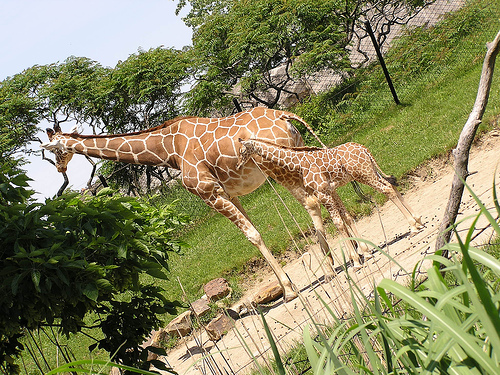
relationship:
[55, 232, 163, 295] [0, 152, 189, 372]
leaves on tree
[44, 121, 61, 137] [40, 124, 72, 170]
horn on top head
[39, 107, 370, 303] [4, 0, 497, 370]
giraffe in enclosure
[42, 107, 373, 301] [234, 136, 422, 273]
giraffe protecting giraffe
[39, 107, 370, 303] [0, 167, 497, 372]
giraffe close to bushes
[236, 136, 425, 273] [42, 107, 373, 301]
giraffe standing near giraffe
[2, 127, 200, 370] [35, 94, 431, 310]
tree near giraffes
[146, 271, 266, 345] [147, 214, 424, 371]
rocks on ground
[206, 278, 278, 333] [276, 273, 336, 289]
rocks by feet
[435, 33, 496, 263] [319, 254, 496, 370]
stick by grass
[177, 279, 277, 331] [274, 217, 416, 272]
rocks near feet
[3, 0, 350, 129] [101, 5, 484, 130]
trees behind fence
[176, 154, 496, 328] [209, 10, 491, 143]
patch in grass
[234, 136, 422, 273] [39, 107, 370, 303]
giraffe near giraffe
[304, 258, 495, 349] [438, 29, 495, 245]
grass near stick